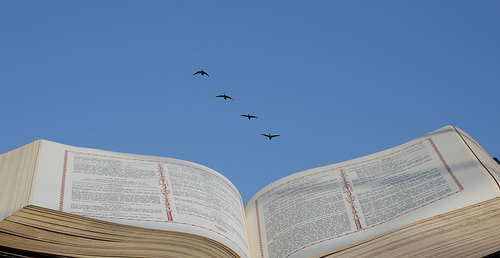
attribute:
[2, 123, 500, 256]
book — open, trimmed, white, detailed, large, lined, fat, big, thick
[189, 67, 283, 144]
bird — large, flying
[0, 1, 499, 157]
sky — blue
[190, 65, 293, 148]
birds — flying, black